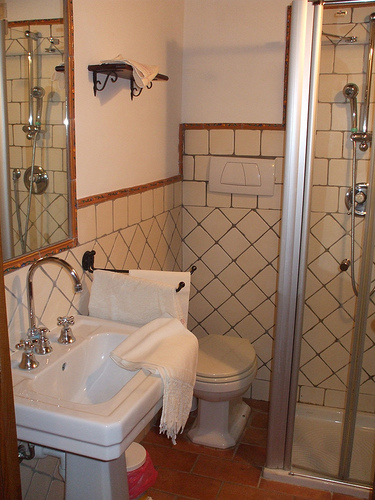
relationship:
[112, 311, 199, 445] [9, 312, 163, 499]
towel hanging over sink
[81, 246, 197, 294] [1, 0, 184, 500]
towel rack attached to wall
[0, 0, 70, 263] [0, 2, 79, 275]
mirror has frame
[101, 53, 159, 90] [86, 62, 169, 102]
towel on top of shelf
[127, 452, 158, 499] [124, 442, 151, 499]
bag inside of trashcan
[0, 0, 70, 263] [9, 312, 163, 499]
mirror above sink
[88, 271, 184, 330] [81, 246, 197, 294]
towel on towel rack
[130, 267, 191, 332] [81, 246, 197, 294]
towel on towel rack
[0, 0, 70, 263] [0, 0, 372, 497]
mirror inside of bathroom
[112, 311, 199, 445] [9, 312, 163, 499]
towel hanging on sink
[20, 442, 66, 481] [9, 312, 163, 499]
pipes underneath sink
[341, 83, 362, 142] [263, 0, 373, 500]
shower head inside of shower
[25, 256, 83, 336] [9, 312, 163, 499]
faucet attached to sink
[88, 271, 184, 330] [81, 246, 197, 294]
towel hanging from towel rack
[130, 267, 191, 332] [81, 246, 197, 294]
towel hanging from towel rack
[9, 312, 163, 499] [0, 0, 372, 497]
sink inside bathroom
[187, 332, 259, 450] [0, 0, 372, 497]
toilet inside of bathroom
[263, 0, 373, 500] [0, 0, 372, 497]
shower inside of bathroom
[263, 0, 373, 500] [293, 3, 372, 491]
shower has doors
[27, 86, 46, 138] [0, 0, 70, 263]
shower head inside of mirror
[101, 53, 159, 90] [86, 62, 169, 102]
towel folded on shelf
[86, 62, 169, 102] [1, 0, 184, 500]
shelf attached to wall